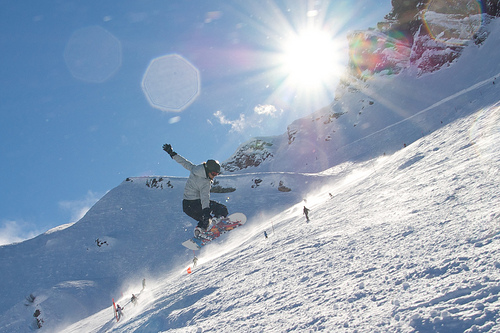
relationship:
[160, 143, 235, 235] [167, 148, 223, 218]
snowboarder wears jacket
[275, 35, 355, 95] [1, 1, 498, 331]
sun shining over hill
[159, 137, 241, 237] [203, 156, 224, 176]
snowboarder wearing helmet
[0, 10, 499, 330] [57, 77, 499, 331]
snow on ground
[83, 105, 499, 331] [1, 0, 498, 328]
snow on ground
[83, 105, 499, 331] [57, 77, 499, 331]
snow on ground